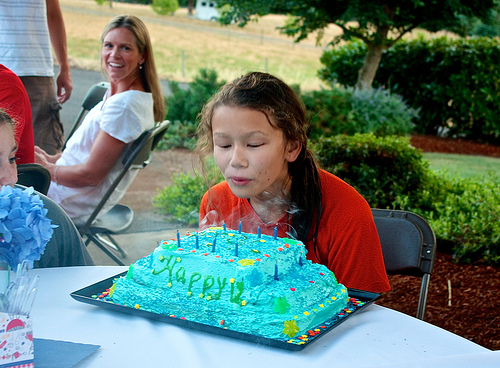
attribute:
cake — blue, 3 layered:
[73, 216, 391, 355]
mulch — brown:
[451, 281, 484, 326]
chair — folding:
[355, 205, 435, 319]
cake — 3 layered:
[121, 198, 335, 341]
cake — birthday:
[90, 215, 357, 346]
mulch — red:
[380, 253, 499, 350]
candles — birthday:
[156, 213, 306, 285]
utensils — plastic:
[7, 262, 41, 327]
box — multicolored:
[3, 326, 37, 362]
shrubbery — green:
[323, 19, 498, 131]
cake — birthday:
[106, 215, 354, 341]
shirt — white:
[46, 88, 153, 225]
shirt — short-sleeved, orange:
[197, 163, 390, 295]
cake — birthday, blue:
[108, 226, 350, 339]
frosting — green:
[101, 215, 353, 345]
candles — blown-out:
[175, 217, 305, 281]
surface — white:
[2, 263, 496, 364]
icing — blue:
[112, 223, 348, 339]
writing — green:
[152, 251, 246, 306]